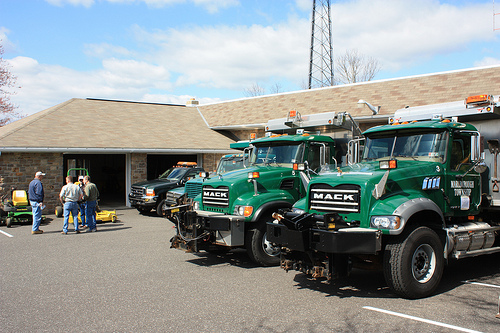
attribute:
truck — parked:
[198, 137, 300, 261]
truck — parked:
[337, 112, 489, 284]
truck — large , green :
[191, 104, 344, 264]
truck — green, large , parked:
[266, 93, 498, 298]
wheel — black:
[386, 222, 453, 308]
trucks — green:
[211, 133, 493, 303]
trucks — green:
[181, 86, 498, 304]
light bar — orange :
[175, 158, 197, 167]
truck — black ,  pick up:
[130, 162, 195, 219]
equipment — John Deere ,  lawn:
[9, 175, 54, 252]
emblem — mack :
[304, 182, 359, 214]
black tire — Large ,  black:
[392, 225, 450, 300]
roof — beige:
[56, 101, 196, 136]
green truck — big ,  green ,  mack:
[177, 128, 339, 264]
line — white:
[359, 300, 485, 332]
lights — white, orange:
[369, 208, 405, 233]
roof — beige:
[1, 63, 498, 153]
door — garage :
[68, 150, 135, 212]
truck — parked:
[279, 86, 496, 284]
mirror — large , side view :
[467, 135, 477, 163]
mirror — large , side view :
[345, 137, 356, 163]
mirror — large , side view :
[319, 145, 330, 170]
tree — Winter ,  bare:
[332, 49, 379, 84]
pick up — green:
[191, 107, 368, 268]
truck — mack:
[163, 131, 257, 251]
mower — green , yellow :
[3, 185, 36, 231]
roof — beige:
[17, 65, 494, 149]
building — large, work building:
[2, 65, 498, 219]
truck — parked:
[274, 87, 494, 305]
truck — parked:
[194, 89, 321, 263]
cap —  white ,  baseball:
[26, 165, 56, 179]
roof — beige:
[202, 68, 499, 123]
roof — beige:
[0, 97, 243, 148]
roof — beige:
[204, 62, 490, 128]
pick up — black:
[122, 149, 202, 220]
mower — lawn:
[0, 203, 45, 226]